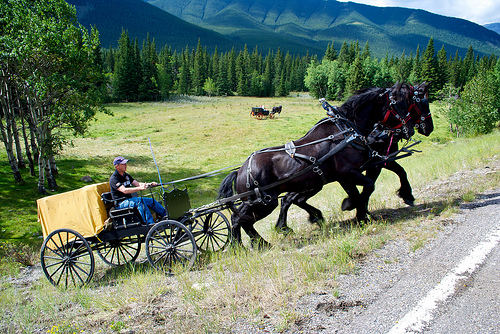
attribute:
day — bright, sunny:
[16, 5, 488, 332]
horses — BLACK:
[222, 77, 433, 248]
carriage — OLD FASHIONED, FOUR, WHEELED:
[35, 179, 227, 289]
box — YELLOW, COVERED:
[32, 179, 112, 249]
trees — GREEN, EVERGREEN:
[107, 27, 476, 90]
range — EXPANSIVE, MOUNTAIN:
[118, 6, 447, 60]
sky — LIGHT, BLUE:
[403, 6, 482, 29]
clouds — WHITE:
[472, 6, 482, 17]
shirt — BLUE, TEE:
[109, 176, 135, 200]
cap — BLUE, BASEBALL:
[112, 154, 132, 165]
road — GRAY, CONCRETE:
[389, 222, 485, 322]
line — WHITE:
[410, 238, 481, 326]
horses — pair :
[211, 81, 434, 231]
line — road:
[389, 233, 464, 332]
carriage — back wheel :
[14, 120, 231, 285]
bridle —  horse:
[276, 79, 431, 200]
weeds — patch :
[137, 248, 342, 293]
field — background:
[77, 88, 314, 168]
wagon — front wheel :
[22, 177, 202, 291]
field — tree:
[121, 88, 300, 167]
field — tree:
[108, 83, 294, 156]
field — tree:
[74, 91, 285, 178]